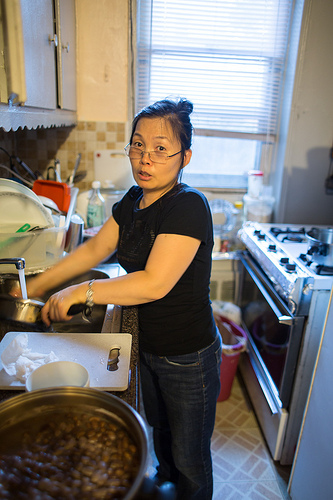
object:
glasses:
[123, 141, 186, 162]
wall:
[277, 93, 314, 122]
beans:
[48, 416, 107, 459]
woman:
[62, 91, 265, 484]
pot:
[300, 224, 331, 269]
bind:
[214, 308, 251, 405]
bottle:
[243, 169, 265, 198]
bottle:
[241, 196, 275, 223]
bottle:
[220, 208, 243, 248]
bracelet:
[69, 274, 103, 314]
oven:
[235, 220, 329, 412]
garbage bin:
[211, 308, 246, 403]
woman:
[51, 82, 230, 495]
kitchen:
[51, 5, 333, 492]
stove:
[242, 216, 330, 302]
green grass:
[111, 93, 195, 239]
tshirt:
[98, 178, 242, 364]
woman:
[96, 97, 211, 254]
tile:
[0, 123, 126, 187]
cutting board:
[2, 331, 132, 391]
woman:
[100, 95, 206, 297]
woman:
[109, 112, 216, 327]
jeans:
[152, 317, 222, 444]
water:
[18, 278, 36, 294]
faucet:
[1, 230, 31, 286]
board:
[6, 324, 133, 387]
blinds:
[133, 0, 308, 142]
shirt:
[113, 187, 220, 353]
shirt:
[108, 181, 216, 357]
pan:
[1, 288, 48, 327]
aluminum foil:
[236, 226, 307, 309]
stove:
[236, 220, 332, 467]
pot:
[0, 291, 93, 326]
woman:
[44, 92, 227, 379]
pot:
[14, 269, 110, 349]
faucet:
[2, 259, 31, 311]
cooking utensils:
[0, 155, 80, 258]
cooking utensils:
[0, 328, 133, 385]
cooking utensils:
[0, 299, 87, 322]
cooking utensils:
[1, 388, 150, 497]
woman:
[125, 96, 196, 200]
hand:
[42, 284, 78, 330]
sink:
[2, 250, 126, 348]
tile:
[230, 465, 258, 488]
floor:
[219, 400, 268, 494]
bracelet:
[82, 280, 93, 310]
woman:
[122, 103, 223, 409]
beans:
[0, 413, 136, 495]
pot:
[0, 387, 177, 499]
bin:
[213, 307, 248, 402]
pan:
[4, 299, 87, 328]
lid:
[233, 200, 244, 209]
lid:
[247, 169, 264, 178]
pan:
[6, 297, 93, 327]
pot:
[0, 384, 153, 500]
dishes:
[2, 178, 61, 233]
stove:
[234, 221, 323, 463]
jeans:
[135, 329, 222, 498]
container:
[25, 359, 89, 391]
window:
[134, 1, 296, 194]